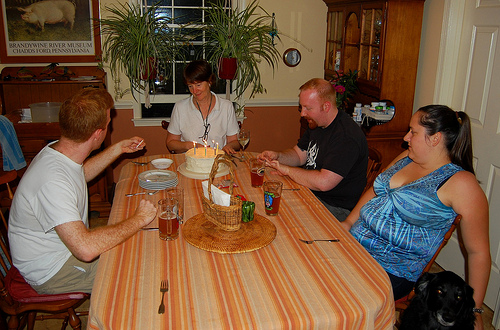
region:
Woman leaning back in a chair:
[338, 104, 492, 328]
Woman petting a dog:
[337, 103, 491, 328]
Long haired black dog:
[393, 269, 475, 328]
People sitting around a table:
[7, 55, 488, 329]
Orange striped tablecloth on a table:
[87, 148, 397, 328]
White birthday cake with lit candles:
[174, 138, 232, 178]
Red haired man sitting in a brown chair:
[1, 85, 158, 329]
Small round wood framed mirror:
[281, 46, 302, 69]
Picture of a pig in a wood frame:
[0, 0, 102, 64]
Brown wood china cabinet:
[297, 0, 424, 206]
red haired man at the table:
[16, 80, 136, 295]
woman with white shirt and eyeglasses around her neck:
[165, 53, 239, 160]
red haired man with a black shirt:
[253, 73, 370, 209]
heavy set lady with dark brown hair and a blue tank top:
[358, 92, 489, 280]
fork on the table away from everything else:
[149, 275, 176, 317]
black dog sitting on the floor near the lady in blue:
[395, 265, 480, 325]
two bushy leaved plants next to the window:
[93, 4, 285, 75]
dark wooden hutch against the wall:
[314, 3, 414, 99]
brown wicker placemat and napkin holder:
[192, 178, 268, 257]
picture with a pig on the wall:
[5, 1, 97, 56]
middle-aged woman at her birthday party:
[165, 60, 240, 145]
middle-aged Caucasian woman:
[165, 60, 241, 144]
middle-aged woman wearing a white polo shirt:
[166, 61, 241, 145]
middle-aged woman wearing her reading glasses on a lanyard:
[165, 59, 240, 144]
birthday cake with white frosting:
[184, 140, 222, 175]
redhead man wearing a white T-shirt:
[8, 88, 157, 262]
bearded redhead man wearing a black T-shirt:
[257, 78, 366, 170]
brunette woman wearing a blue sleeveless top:
[348, 105, 487, 239]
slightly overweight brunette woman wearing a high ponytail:
[350, 104, 490, 241]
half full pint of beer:
[158, 196, 181, 241]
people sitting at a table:
[11, 60, 491, 324]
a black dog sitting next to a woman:
[398, 269, 475, 329]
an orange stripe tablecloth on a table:
[93, 150, 395, 329]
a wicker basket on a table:
[200, 154, 244, 231]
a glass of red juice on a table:
[262, 180, 284, 216]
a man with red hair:
[56, 82, 113, 158]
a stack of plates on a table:
[137, 168, 177, 189]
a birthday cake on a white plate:
[178, 138, 230, 180]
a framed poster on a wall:
[0, 0, 100, 67]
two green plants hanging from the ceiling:
[88, 3, 284, 108]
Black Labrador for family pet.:
[392, 267, 483, 327]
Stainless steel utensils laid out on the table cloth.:
[123, 154, 342, 314]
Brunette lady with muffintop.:
[339, 91, 486, 326]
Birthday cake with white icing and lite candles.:
[176, 140, 235, 180]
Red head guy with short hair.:
[8, 86, 159, 293]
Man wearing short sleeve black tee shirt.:
[258, 71, 369, 218]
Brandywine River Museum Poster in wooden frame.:
[2, 1, 105, 69]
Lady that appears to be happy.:
[166, 57, 245, 155]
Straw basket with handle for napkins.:
[197, 150, 246, 233]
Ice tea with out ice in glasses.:
[158, 156, 282, 241]